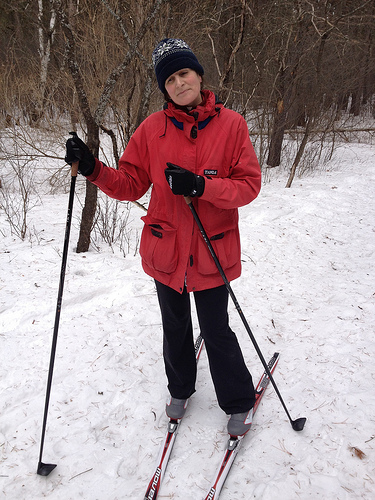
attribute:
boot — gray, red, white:
[161, 389, 189, 421]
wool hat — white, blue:
[148, 35, 209, 84]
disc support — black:
[292, 414, 309, 432]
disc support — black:
[36, 459, 57, 477]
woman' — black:
[64, 21, 298, 439]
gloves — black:
[55, 136, 226, 217]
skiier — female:
[52, 32, 302, 495]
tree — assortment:
[230, 20, 368, 102]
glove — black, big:
[163, 156, 217, 203]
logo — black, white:
[202, 168, 220, 173]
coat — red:
[100, 108, 264, 290]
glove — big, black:
[62, 130, 205, 196]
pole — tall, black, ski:
[36, 176, 76, 476]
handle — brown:
[69, 160, 79, 176]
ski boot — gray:
[164, 390, 193, 420]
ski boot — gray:
[225, 407, 255, 434]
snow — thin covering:
[300, 223, 374, 429]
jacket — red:
[87, 86, 261, 293]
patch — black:
[202, 166, 218, 176]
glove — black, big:
[162, 160, 205, 200]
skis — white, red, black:
[128, 320, 279, 494]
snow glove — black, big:
[162, 159, 204, 198]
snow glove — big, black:
[65, 127, 95, 176]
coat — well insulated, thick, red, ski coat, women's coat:
[82, 87, 263, 296]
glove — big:
[164, 160, 204, 197]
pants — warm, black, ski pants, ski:
[151, 276, 258, 418]